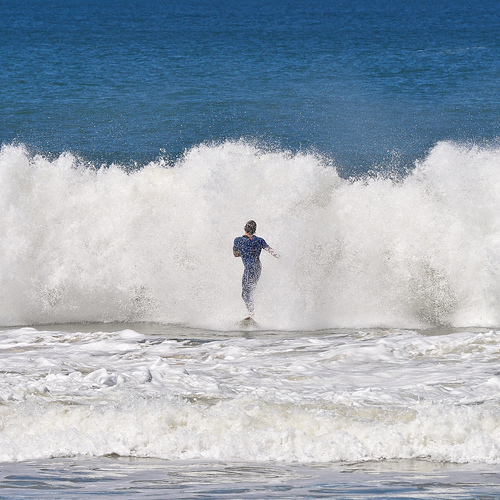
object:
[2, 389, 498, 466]
wave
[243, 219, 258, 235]
hair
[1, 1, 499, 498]
ocean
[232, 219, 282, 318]
man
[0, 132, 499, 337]
wave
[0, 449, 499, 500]
shore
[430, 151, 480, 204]
ground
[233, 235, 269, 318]
wet suit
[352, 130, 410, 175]
spray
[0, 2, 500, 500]
water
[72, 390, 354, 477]
foam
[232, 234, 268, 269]
blue shirt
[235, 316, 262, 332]
board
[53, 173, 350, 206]
splash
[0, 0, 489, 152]
calm/blue water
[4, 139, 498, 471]
portion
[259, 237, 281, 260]
arm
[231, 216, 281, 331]
surfing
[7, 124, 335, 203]
spray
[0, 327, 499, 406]
waves